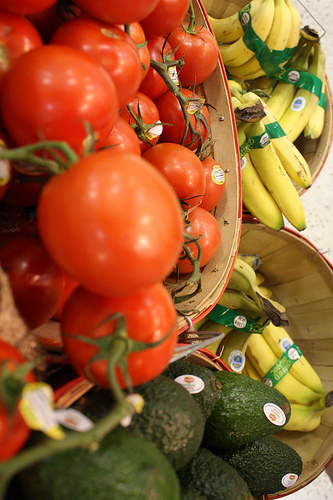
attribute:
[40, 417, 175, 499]
avacado — green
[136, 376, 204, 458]
avacado — green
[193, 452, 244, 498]
avacado — green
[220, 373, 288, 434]
avacado — green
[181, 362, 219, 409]
avacado — green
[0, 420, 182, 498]
avocado — green, bumpy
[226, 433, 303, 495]
avacado — green, dark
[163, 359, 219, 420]
avacado — green, dark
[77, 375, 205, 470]
avacado — green, dark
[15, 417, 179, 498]
avacado — green, dark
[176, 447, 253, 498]
avacado — dark, green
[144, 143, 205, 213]
tomato — ripe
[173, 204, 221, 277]
tomato — ripe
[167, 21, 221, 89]
tomato — ripe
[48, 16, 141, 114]
tomato — ripe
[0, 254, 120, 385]
tomato — red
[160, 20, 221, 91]
tomato — red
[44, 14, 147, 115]
tomato — red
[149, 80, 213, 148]
tomato — red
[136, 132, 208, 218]
tomato — red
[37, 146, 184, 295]
tomato — ripe, red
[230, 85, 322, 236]
banana — yellow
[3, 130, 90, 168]
stem — green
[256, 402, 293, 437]
sticker — white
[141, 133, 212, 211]
tomato — red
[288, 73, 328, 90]
stripe — green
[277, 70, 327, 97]
stripe — green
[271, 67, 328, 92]
stripe — green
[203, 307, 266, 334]
stripe — green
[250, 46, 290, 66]
stripe — green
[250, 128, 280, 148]
stripe — green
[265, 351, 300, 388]
stripe — green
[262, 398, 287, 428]
sticker — oval, white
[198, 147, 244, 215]
tomato — red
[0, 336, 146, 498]
stem — long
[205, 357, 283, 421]
avocado — green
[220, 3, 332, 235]
bananas — yellow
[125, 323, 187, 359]
leaf — green, narrow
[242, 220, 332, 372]
basket — brown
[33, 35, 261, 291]
tomaaaaaaatoes — green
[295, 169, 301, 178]
bruise — brown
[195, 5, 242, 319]
trim — red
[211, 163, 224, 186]
sticker — yellow, white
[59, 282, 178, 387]
tomato — red